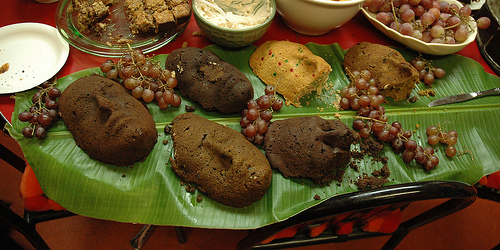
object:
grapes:
[399, 7, 415, 22]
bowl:
[359, 2, 479, 50]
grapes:
[406, 139, 418, 153]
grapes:
[444, 146, 456, 158]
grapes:
[422, 74, 434, 87]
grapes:
[339, 98, 349, 109]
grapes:
[245, 125, 255, 137]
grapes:
[141, 88, 153, 104]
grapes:
[17, 109, 31, 122]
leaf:
[6, 38, 499, 225]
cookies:
[164, 45, 254, 115]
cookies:
[260, 114, 358, 192]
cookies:
[254, 39, 332, 105]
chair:
[243, 167, 477, 250]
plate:
[1, 22, 70, 96]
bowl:
[188, 0, 278, 32]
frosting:
[205, 1, 266, 22]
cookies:
[55, 71, 157, 164]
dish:
[51, 1, 193, 59]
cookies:
[162, 107, 281, 210]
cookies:
[342, 40, 424, 107]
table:
[3, 1, 500, 207]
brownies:
[172, 2, 189, 19]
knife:
[427, 87, 498, 108]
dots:
[278, 61, 282, 66]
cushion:
[377, 212, 395, 225]